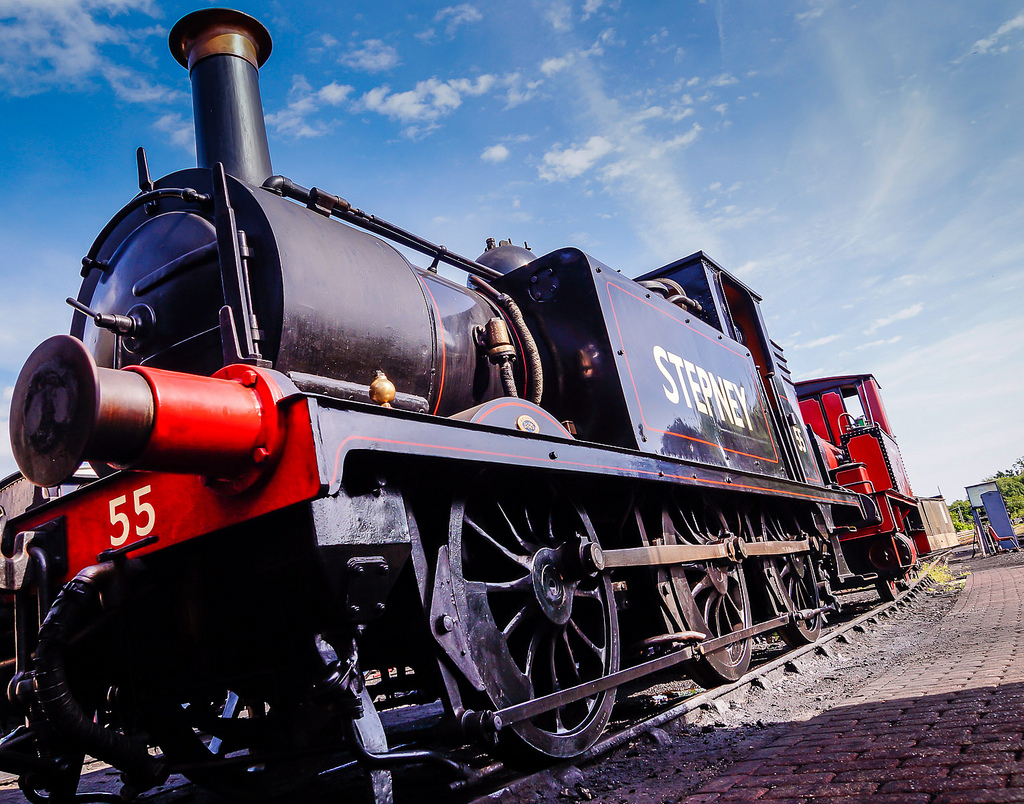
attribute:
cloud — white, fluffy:
[538, 137, 608, 188]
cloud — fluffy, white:
[359, 76, 503, 143]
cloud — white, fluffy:
[280, 67, 462, 147]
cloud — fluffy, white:
[310, 26, 394, 74]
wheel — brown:
[640, 495, 764, 688]